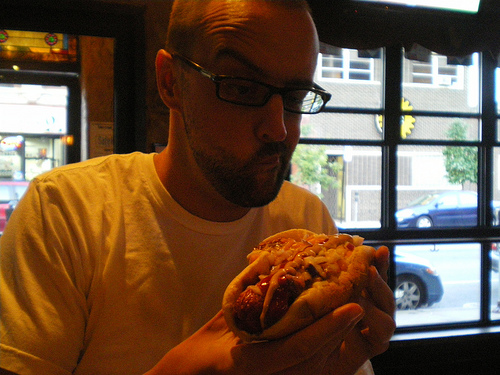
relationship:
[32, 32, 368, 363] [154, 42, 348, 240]
man makes face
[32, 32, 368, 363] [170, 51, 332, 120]
man has glasses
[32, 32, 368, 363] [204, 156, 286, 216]
man has beard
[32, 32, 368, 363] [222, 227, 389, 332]
man holds hot dog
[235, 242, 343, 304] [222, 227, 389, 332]
ketchup on hot dog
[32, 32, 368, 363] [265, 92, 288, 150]
man has nose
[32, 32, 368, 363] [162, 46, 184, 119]
man has ear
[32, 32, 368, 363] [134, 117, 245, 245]
man has neck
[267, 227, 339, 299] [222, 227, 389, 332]
cheese on hot dog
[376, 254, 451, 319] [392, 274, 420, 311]
car has front wheel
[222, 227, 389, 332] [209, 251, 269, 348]
hot dog on roll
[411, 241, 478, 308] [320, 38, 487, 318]
road outside window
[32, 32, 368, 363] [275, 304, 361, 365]
man has finger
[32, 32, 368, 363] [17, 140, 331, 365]
man has shirt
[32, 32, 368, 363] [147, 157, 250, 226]
man has collar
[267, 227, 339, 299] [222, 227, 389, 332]
cheese in hot dog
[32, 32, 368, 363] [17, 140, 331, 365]
man wears shirt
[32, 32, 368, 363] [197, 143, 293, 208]
man has beard